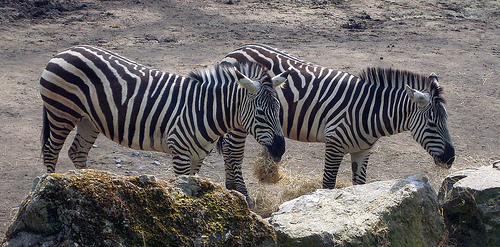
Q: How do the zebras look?
A: They are black and white.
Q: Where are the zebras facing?
A: They are facing to the right.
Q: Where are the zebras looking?
A: They are looking at the rocks.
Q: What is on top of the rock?
A: Moss is on top of the rock.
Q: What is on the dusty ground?
A: Tracks are in the dusty ground.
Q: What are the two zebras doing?
A: They are eating hay.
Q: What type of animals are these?
A: Zebras.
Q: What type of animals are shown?
A: Zebras.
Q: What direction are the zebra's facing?
A: Right.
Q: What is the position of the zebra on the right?
A: Standing.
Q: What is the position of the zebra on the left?
A: Standing.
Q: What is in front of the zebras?
A: Rocks.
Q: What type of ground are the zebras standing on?
A: Bare.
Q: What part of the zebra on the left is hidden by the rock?
A: Front legs and all feet.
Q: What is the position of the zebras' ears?
A: Up.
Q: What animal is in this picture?
A: Zebra.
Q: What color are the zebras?
A: Black and white.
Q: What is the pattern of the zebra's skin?
A: Striped.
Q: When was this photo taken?
A: Daytime.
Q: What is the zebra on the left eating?
A: Grass.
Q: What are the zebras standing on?
A: The ground.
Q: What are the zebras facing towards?
A: Boulders.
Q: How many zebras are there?
A: Two.